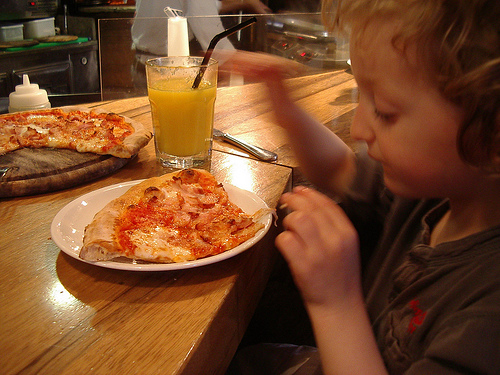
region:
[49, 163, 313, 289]
a slice of pizza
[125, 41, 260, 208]
a glass of orange juice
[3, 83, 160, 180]
a pie of pizza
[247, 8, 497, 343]
a kid eating his pizza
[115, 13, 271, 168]
black straw in the orange juice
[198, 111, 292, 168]
a knife sitting on the table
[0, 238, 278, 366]
a wooden table holding a pizza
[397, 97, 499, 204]
headphones on the kid's ear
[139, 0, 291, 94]
a man cooking pizzas in the kitchen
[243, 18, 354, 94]
a pizza oven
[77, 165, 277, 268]
pizza slice on a white plate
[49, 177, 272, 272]
white plate under pizza slice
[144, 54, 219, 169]
glass behind plate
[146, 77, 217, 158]
glass holds orange juice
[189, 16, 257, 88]
black straw in glass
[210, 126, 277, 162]
silver knife behind glass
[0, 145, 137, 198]
wooden cutting board behind plate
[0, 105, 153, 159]
pizza on cutting board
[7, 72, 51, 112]
squeeze bottle behind pizza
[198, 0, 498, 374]
child is eating pizza slice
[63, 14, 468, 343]
Little boy sitting at table eating pizza.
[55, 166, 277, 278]
Slice of pizza on white plate.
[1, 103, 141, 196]
Pizza sitting on wood serving plate.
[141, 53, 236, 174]
Glass of orange juice sitting on table.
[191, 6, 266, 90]
Black plastic straw in glass of orange juice.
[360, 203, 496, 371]
Little boy dressed in brown shirt.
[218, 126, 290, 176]
Handle of knife lying on table.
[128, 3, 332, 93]
Man in background making pizzas.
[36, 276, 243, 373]
Edge of brown wood table.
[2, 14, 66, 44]
White plastic bins in background.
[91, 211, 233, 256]
a piece of pizza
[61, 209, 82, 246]
a beautiful white plate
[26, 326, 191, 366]
a smooth wooden table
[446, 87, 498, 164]
a long haired girl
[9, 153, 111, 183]
a grey colored board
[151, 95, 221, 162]
an orange colored drink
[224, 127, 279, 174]
a shiny metal knife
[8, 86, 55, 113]
a white bottle top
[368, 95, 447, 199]
a brown colored girl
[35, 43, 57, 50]
a green colored counter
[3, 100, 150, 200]
pizza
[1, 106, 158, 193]
the pizza is on a chopping board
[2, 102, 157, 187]
a large slice is missing from the pizza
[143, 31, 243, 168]
a glass of juice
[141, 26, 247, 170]
a straw is in the glass of juice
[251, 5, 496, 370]
a boy sits at the table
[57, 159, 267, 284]
a large slice of pizza on a plate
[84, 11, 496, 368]
the boy is about to eat the pizza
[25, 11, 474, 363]
the boy is sitting at a wooden bar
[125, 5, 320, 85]
a man behind the counter is cooking